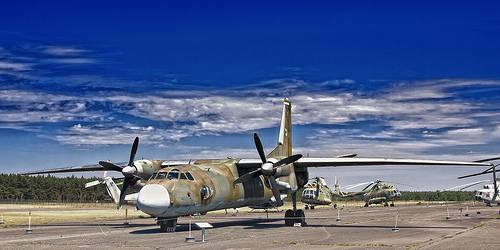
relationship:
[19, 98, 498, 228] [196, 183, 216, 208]
rust on plane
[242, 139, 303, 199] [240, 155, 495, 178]
blades on wing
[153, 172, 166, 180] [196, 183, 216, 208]
window on front of plane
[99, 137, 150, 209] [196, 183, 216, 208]
propeller on plane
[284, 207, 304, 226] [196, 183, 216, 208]
wheels under plane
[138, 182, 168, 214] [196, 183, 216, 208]
nose on plane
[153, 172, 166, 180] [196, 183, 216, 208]
window on plane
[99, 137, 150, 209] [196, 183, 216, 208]
propeller of plane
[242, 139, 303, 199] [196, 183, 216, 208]
blades on plane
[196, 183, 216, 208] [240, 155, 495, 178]
plane has wing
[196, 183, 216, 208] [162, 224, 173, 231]
plane has wheels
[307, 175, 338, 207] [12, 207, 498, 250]
helicopter on pavement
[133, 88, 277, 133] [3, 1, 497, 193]
clouds in sky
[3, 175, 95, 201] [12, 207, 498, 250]
trees next to pavement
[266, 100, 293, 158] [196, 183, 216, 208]
tail on plane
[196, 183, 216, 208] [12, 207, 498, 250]
plane on pavement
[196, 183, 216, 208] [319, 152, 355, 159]
plane has fin